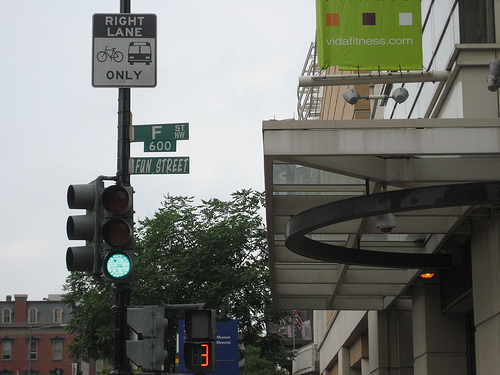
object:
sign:
[91, 13, 157, 88]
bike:
[97, 46, 124, 63]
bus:
[128, 42, 152, 65]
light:
[107, 254, 131, 278]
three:
[201, 344, 208, 366]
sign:
[316, 0, 423, 71]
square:
[326, 13, 339, 26]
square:
[363, 13, 376, 25]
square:
[399, 13, 413, 26]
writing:
[326, 37, 414, 45]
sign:
[132, 123, 189, 152]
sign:
[132, 157, 189, 174]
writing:
[149, 125, 186, 151]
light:
[420, 273, 435, 278]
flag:
[292, 310, 304, 331]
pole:
[293, 310, 295, 351]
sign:
[215, 321, 239, 375]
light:
[100, 185, 136, 283]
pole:
[116, 88, 131, 186]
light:
[66, 175, 104, 277]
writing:
[105, 16, 144, 36]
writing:
[107, 70, 143, 79]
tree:
[59, 188, 299, 375]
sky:
[0, 0, 327, 338]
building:
[0, 294, 104, 375]